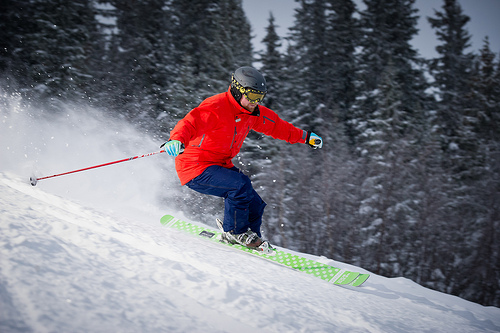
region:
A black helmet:
[232, 62, 267, 95]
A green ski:
[156, 212, 389, 297]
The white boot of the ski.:
[214, 219, 279, 257]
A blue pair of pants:
[192, 157, 277, 237]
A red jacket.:
[157, 87, 310, 181]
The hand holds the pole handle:
[159, 136, 192, 159]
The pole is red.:
[22, 141, 164, 204]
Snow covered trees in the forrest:
[358, 108, 482, 268]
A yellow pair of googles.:
[233, 75, 268, 103]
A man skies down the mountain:
[27, 14, 394, 309]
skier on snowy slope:
[127, 64, 344, 254]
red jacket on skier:
[160, 96, 307, 192]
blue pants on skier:
[188, 153, 264, 237]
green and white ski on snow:
[163, 208, 371, 289]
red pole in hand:
[62, 142, 184, 182]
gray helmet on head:
[225, 62, 265, 95]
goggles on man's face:
[239, 84, 266, 105]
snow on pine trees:
[334, 65, 401, 187]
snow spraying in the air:
[18, 101, 118, 146]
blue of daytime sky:
[465, 5, 496, 39]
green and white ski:
[152, 207, 382, 287]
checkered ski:
[156, 200, 361, 286]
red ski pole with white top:
[22, 145, 182, 185]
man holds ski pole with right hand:
[152, 130, 184, 158]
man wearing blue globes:
[165, 133, 185, 161]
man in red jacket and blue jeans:
[176, 84, 307, 240]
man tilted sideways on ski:
[154, 60, 381, 285]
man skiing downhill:
[142, 56, 375, 298]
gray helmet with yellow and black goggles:
[226, 56, 269, 114]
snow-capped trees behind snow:
[4, 0, 499, 300]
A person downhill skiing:
[30, 43, 449, 300]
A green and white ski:
[149, 203, 384, 291]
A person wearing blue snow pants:
[177, 156, 306, 270]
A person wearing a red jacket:
[169, 77, 333, 195]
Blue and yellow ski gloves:
[157, 136, 191, 165]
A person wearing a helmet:
[213, 51, 268, 123]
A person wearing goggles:
[215, 57, 275, 119]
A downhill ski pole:
[12, 141, 192, 196]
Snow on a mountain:
[0, 155, 443, 329]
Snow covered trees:
[264, 60, 499, 291]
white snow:
[98, 262, 158, 323]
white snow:
[110, 261, 195, 318]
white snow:
[132, 247, 223, 302]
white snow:
[125, 220, 206, 288]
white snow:
[140, 264, 192, 308]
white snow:
[82, 244, 189, 301]